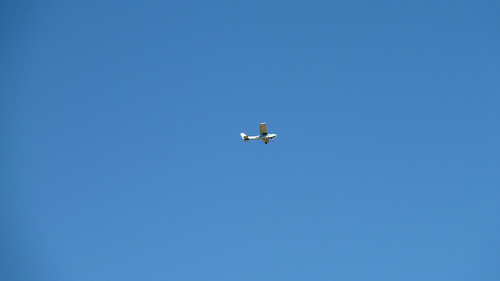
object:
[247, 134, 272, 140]
body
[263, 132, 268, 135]
wheel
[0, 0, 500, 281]
blue sky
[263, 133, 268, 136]
rectangular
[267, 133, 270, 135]
window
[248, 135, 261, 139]
side of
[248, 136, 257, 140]
light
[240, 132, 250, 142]
blunt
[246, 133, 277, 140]
oval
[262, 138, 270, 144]
tiny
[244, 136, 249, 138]
dark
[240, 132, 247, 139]
on tail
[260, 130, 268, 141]
under wing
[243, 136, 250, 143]
black dog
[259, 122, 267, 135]
wing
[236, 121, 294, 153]
horizontal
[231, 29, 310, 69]
part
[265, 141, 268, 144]
part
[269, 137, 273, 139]
wheel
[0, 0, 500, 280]
sky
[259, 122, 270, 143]
turbo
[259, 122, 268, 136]
in wing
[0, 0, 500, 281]
clear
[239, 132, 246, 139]
stabilizer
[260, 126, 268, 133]
grey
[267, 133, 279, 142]
front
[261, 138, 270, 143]
wings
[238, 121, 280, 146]
small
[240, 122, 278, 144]
airplane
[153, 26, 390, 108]
no clouds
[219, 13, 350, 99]
clouds